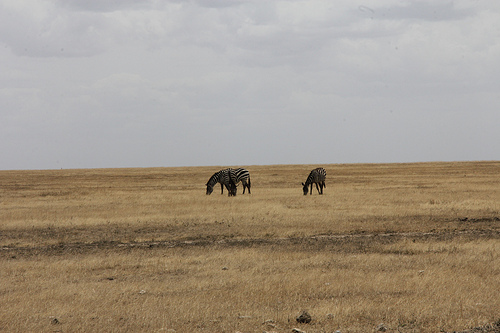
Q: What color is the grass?
A: Brown.